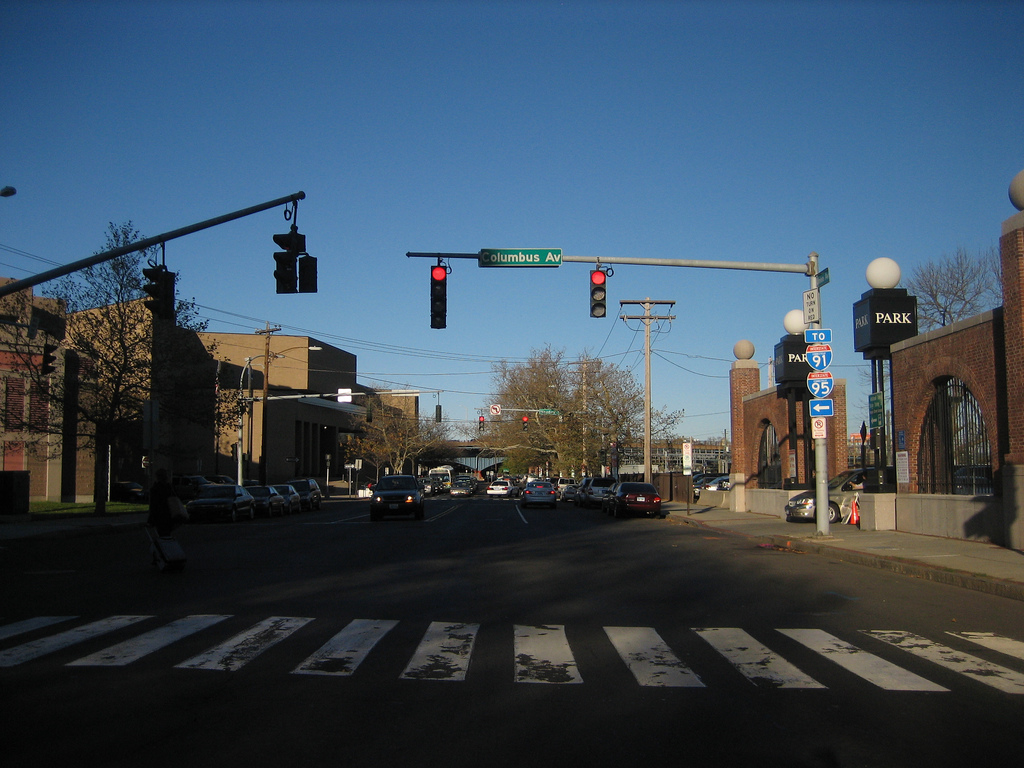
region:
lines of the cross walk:
[10, 550, 1022, 728]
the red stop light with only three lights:
[583, 255, 618, 328]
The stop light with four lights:
[415, 252, 467, 352]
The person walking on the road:
[119, 446, 200, 577]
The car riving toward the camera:
[358, 458, 407, 531]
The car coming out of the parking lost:
[791, 448, 899, 547]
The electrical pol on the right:
[618, 263, 672, 517]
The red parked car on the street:
[608, 474, 654, 528]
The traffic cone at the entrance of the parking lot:
[845, 495, 878, 543]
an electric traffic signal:
[588, 267, 608, 319]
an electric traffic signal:
[430, 261, 450, 331]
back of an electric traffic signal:
[270, 228, 319, 296]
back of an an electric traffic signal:
[140, 263, 175, 317]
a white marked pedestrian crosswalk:
[1, 612, 1022, 695]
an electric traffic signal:
[476, 415, 483, 432]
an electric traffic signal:
[517, 412, 527, 432]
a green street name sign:
[478, 245, 561, 268]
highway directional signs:
[800, 327, 833, 416]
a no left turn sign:
[485, 399, 502, 419]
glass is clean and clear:
[923, 392, 953, 491]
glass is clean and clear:
[927, 379, 970, 398]